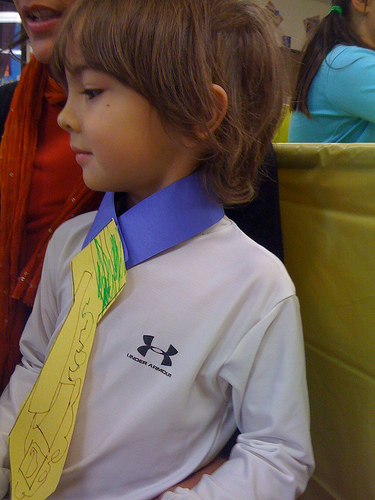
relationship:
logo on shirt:
[136, 331, 180, 371] [1, 210, 316, 499]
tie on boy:
[7, 216, 130, 499] [1, 1, 317, 498]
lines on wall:
[277, 190, 373, 386] [267, 145, 373, 496]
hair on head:
[49, 4, 276, 204] [46, 1, 280, 202]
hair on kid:
[49, 4, 276, 204] [22, 1, 302, 298]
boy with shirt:
[1, 10, 327, 497] [0, 171, 315, 499]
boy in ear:
[1, 10, 327, 497] [191, 82, 227, 140]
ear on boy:
[191, 82, 228, 146] [1, 10, 327, 497]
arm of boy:
[238, 310, 319, 490] [1, 1, 317, 498]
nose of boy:
[56, 96, 81, 131] [1, 1, 317, 498]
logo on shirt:
[123, 337, 196, 393] [4, 178, 336, 483]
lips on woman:
[16, 3, 65, 28] [2, 0, 118, 385]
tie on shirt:
[7, 169, 223, 499] [1, 210, 316, 499]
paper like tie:
[6, 169, 226, 499] [6, 217, 128, 498]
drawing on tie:
[69, 250, 96, 375] [23, 203, 177, 482]